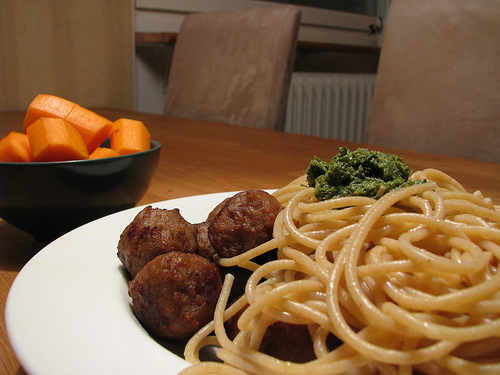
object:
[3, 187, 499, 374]
plate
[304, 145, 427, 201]
green paste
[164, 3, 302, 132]
chair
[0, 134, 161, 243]
bowl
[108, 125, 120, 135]
dark spot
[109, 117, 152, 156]
carrot slice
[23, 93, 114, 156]
carrot slice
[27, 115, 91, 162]
carrot slice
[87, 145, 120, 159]
carrot slice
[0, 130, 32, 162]
carrot slice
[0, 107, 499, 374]
table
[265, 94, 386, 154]
wall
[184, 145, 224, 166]
floor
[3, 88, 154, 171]
grass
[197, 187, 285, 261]
ball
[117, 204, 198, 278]
ball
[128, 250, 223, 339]
ball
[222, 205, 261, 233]
meat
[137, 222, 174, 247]
meat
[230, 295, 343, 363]
balls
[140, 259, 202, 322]
meat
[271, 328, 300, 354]
meat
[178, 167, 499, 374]
noodles